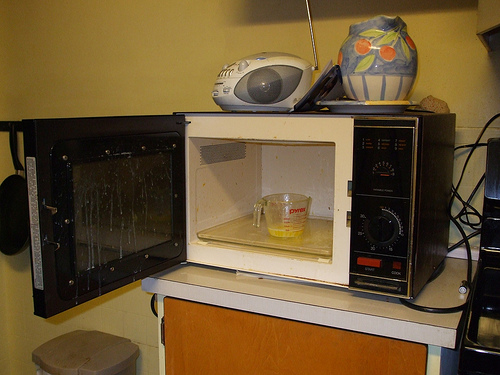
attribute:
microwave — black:
[18, 109, 457, 320]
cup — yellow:
[253, 191, 313, 241]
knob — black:
[365, 212, 396, 243]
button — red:
[356, 256, 383, 270]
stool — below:
[29, 328, 140, 374]